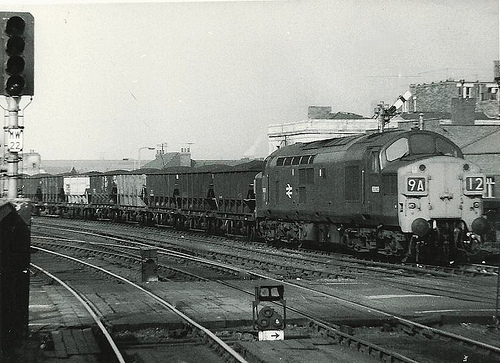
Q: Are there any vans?
A: No, there are no vans.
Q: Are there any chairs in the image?
A: No, there are no chairs.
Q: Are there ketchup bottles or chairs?
A: No, there are no chairs or ketchup bottles.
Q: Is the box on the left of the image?
A: Yes, the box is on the left of the image.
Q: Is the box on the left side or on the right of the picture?
A: The box is on the left of the image.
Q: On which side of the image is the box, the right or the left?
A: The box is on the left of the image.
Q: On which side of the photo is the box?
A: The box is on the left of the image.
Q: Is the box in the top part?
A: No, the box is in the bottom of the image.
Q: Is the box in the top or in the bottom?
A: The box is in the bottom of the image.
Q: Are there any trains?
A: Yes, there is a train.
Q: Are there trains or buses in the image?
A: Yes, there is a train.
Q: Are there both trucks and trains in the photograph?
A: No, there is a train but no trucks.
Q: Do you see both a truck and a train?
A: No, there is a train but no trucks.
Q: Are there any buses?
A: No, there are no buses.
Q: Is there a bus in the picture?
A: No, there are no buses.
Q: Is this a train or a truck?
A: This is a train.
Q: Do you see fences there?
A: No, there are no fences.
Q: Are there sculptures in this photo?
A: No, there are no sculptures.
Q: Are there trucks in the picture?
A: No, there are no trucks.